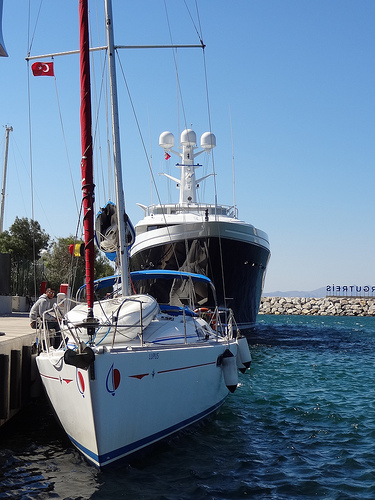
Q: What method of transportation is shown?
A: Boat.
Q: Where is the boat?
A: In the water.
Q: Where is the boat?
A: In the water.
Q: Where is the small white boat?
A: In the water.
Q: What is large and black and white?
A: The yacht.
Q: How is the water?
A: Choppy.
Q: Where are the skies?
A: Over the boats.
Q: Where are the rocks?
A: Out by the jetty.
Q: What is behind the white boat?
A: A black boat.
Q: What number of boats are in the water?
A: Two.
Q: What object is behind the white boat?
A: Large boat.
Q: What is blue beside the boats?
A: Body of water.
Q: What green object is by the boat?
A: Trees.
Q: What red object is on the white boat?
A: Sail.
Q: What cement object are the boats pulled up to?
A: Dock.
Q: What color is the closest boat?
A: White.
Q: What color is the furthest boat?
A: Black and white.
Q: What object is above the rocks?
A: Letters.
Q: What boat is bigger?
A: Black boat.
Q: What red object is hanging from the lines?
A: Flag.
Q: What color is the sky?
A: Blue.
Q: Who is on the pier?
A: Man.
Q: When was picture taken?
A: Daytime.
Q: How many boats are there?
A: Two.